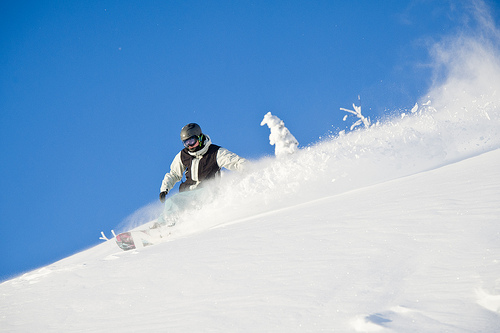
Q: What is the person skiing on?
A: Snow.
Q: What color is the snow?
A: White.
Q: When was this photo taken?
A: Daytime.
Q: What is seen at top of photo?
A: Sky.